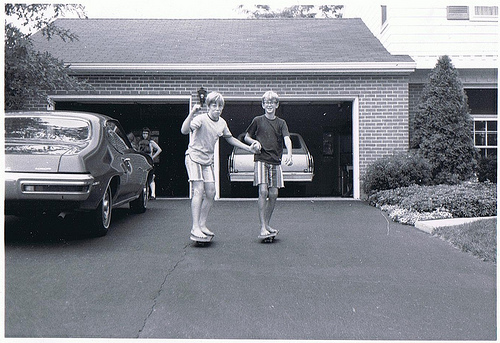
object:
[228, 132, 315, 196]
car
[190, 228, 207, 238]
foot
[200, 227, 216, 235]
foot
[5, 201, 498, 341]
cement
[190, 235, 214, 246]
skateboards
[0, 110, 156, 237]
car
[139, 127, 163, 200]
woman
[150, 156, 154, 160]
hand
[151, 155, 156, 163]
hip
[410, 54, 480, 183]
bush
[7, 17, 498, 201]
house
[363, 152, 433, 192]
bush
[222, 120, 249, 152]
arm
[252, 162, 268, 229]
leg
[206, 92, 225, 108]
hair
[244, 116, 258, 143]
arm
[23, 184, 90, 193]
brake light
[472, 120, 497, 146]
window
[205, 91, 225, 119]
head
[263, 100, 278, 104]
glasses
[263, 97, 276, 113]
face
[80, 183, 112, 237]
tire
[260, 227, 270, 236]
feet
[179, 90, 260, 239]
boy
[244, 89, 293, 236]
boy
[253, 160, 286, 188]
shorts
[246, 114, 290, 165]
tee shirt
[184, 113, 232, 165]
tee shirt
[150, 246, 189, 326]
crack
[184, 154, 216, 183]
shorts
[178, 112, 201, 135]
arm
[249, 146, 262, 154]
hand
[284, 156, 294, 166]
hand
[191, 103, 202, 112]
hand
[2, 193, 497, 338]
driveway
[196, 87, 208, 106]
light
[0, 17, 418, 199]
garage